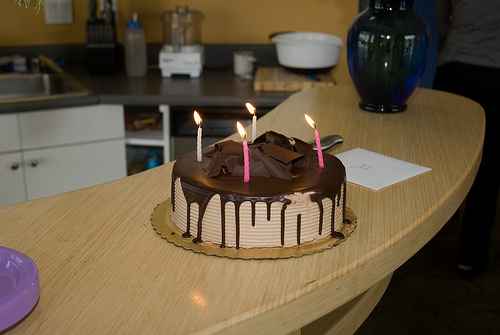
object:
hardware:
[29, 161, 41, 168]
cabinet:
[0, 104, 128, 205]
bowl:
[272, 31, 344, 70]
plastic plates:
[0, 246, 42, 335]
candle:
[313, 130, 324, 169]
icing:
[171, 177, 348, 247]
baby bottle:
[123, 11, 146, 76]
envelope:
[333, 146, 435, 190]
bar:
[3, 82, 485, 333]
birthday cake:
[173, 125, 359, 250]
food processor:
[157, 5, 207, 79]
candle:
[196, 126, 203, 161]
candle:
[252, 116, 257, 142]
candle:
[243, 141, 251, 180]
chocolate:
[168, 130, 353, 249]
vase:
[343, 1, 433, 113]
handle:
[312, 133, 342, 152]